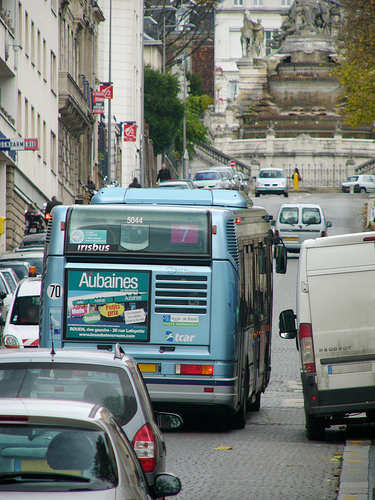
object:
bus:
[40, 179, 290, 429]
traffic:
[0, 160, 358, 494]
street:
[80, 177, 361, 486]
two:
[0, 349, 168, 498]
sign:
[124, 307, 148, 326]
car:
[284, 230, 373, 437]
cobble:
[279, 485, 294, 498]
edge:
[362, 441, 374, 499]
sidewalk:
[327, 441, 372, 499]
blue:
[213, 327, 221, 351]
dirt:
[316, 363, 327, 388]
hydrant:
[291, 167, 300, 190]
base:
[235, 61, 265, 104]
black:
[71, 303, 87, 318]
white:
[43, 283, 57, 301]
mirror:
[275, 246, 288, 273]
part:
[204, 424, 308, 487]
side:
[273, 247, 288, 275]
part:
[144, 363, 149, 372]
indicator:
[204, 363, 214, 375]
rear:
[3, 422, 35, 447]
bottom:
[303, 402, 369, 419]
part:
[12, 136, 40, 155]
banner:
[0, 140, 37, 150]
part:
[106, 123, 116, 159]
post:
[107, 2, 113, 191]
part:
[192, 92, 204, 132]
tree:
[341, 6, 374, 134]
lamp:
[108, 6, 120, 25]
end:
[242, 176, 347, 204]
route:
[166, 223, 205, 247]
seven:
[184, 226, 195, 247]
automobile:
[0, 396, 153, 498]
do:
[227, 158, 238, 170]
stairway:
[188, 99, 265, 168]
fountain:
[217, 105, 342, 144]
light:
[174, 363, 188, 377]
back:
[40, 203, 235, 398]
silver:
[6, 338, 179, 499]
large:
[239, 8, 271, 67]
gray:
[208, 436, 235, 480]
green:
[152, 81, 194, 130]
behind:
[142, 10, 375, 127]